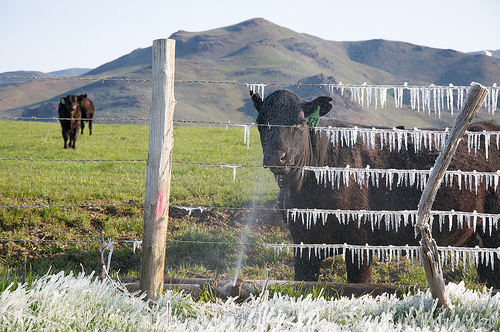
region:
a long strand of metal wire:
[1, 73, 498, 98]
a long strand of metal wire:
[1, 114, 498, 146]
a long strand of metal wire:
[0, 155, 498, 177]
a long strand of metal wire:
[4, 203, 499, 220]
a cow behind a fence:
[244, 81, 495, 329]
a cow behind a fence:
[56, 93, 87, 150]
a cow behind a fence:
[69, 92, 96, 132]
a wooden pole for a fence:
[140, 34, 179, 309]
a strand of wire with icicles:
[240, 78, 498, 114]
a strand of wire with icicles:
[310, 121, 497, 159]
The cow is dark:
[219, 68, 364, 207]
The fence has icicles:
[301, 188, 455, 295]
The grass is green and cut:
[49, 162, 214, 312]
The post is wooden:
[130, 32, 180, 317]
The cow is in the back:
[45, 65, 125, 187]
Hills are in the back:
[185, 22, 405, 107]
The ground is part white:
[56, 272, 196, 326]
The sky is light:
[16, 18, 106, 69]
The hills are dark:
[269, 37, 451, 155]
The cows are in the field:
[34, 80, 424, 320]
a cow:
[261, 94, 305, 166]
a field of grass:
[47, 151, 122, 195]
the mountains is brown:
[229, 34, 287, 84]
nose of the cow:
[267, 149, 288, 166]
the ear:
[311, 98, 332, 113]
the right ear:
[244, 89, 261, 106]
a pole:
[143, 193, 165, 293]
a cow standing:
[57, 97, 84, 147]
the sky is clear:
[95, 25, 139, 48]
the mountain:
[374, 43, 421, 64]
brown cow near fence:
[267, 84, 496, 284]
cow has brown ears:
[270, 55, 331, 128]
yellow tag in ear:
[292, 101, 337, 142]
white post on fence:
[150, 59, 180, 308]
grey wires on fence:
[221, 65, 472, 322]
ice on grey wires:
[230, 53, 497, 284]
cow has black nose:
[268, 149, 289, 171]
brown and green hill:
[72, 44, 249, 136]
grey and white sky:
[8, 7, 121, 67]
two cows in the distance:
[55, 85, 95, 145]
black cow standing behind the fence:
[247, 80, 499, 296]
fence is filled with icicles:
[2, 70, 496, 320]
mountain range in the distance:
[0, 23, 495, 126]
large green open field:
[1, 123, 276, 287]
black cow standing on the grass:
[240, 80, 493, 283]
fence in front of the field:
[10, 69, 497, 316]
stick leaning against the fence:
[400, 81, 485, 313]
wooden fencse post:
[136, 24, 179, 303]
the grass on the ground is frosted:
[5, 271, 492, 329]